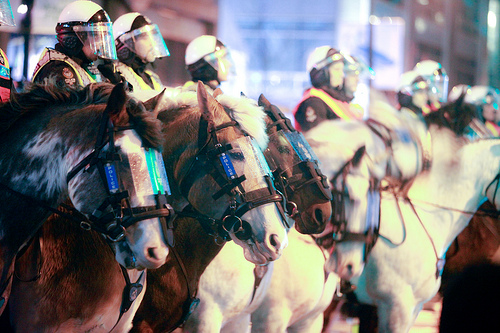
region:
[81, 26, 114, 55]
reflection on the face mask.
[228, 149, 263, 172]
shield in front of horse's eyes.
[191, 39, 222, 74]
helmet on policeman's head.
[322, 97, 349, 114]
reflective vest on policeman.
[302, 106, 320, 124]
logo on policeman's jacket.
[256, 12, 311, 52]
building in the background.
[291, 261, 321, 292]
chest of white horse.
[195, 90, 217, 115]
right ear of the horse.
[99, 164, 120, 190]
writing on facial shield.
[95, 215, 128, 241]
reigns on the horse.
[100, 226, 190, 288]
the horse's mouth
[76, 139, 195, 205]
the horse's protective shield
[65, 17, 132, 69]
the policeman's protective shield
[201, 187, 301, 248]
leather straps on the horse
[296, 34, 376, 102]
helmet on the policeman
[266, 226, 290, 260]
horse's nose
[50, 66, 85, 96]
patches on the policeman's jacket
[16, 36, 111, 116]
policeman is wearing a reflective vest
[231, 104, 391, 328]
the horse is white and large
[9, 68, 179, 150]
horse's brown mane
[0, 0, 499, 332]
mounted police in full riot gear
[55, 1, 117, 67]
a police riot gear helmet and visor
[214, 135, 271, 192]
horses with eye protection gear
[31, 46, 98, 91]
a bullet proof vest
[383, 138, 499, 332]
a white police horse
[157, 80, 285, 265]
a palomino police horse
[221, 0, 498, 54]
city buildings in the background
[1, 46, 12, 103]
a yellow and orange police vest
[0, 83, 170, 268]
a brown and white splotched horse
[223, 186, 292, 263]
the horse's reigns attached to the mouth bit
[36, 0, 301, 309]
POLICE ON HORSES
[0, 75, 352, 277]
A ROW OF HORSES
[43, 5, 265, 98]
COPS WITH FACE SHIELDS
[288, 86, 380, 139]
YELLOW AND RED VESTS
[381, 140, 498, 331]
A WHITE HORSE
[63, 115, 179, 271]
A BLACK BRIDLE ON HORSE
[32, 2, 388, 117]
5 POLICE OFFICERS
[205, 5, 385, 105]
BUILDING WITH WINDOW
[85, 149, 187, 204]
BLUE AND GREEN SHIELDS ON BRIDLE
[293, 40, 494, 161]
A GROUP OF COPS ON HORSES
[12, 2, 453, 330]
horses in a line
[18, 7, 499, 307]
people on the horses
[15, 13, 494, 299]
cops on the horses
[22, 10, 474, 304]
police on the horses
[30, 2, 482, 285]
police officers on the horses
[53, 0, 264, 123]
police officers wearing helmets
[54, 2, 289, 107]
people wearing helments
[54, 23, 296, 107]
cops with helmets and mask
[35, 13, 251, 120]
people with helmets and mask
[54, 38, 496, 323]
brown and white horses